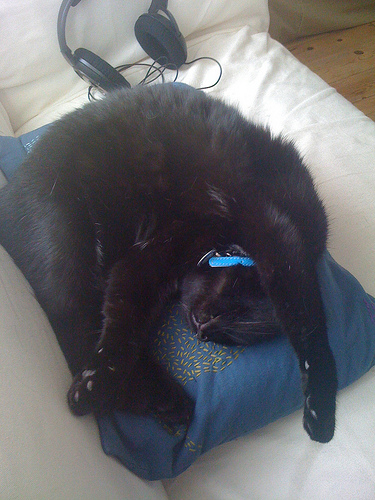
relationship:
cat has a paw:
[4, 90, 337, 444] [70, 350, 118, 408]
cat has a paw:
[4, 90, 337, 444] [298, 365, 339, 444]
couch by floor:
[2, 7, 373, 497] [270, 2, 371, 122]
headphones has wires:
[57, 0, 225, 94] [89, 55, 222, 99]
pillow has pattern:
[2, 84, 375, 483] [142, 293, 271, 452]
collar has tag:
[197, 247, 261, 268] [198, 248, 214, 267]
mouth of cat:
[187, 301, 227, 337] [4, 90, 337, 444]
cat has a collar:
[4, 90, 337, 444] [197, 247, 261, 268]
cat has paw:
[4, 90, 337, 444] [298, 370, 339, 444]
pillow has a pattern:
[2, 84, 375, 483] [142, 293, 271, 452]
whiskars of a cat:
[163, 313, 285, 358] [4, 90, 337, 444]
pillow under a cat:
[2, 84, 375, 483] [4, 90, 337, 444]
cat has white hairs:
[4, 90, 337, 444] [92, 186, 241, 267]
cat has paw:
[4, 90, 337, 444] [70, 350, 118, 408]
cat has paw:
[4, 90, 337, 444] [298, 365, 339, 444]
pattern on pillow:
[142, 293, 271, 452] [2, 84, 375, 483]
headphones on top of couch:
[57, 0, 225, 94] [2, 7, 373, 497]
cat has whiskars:
[4, 90, 337, 444] [163, 313, 285, 358]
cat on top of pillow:
[4, 90, 337, 444] [2, 84, 375, 483]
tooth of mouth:
[210, 313, 216, 318] [187, 301, 227, 337]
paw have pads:
[298, 370, 339, 444] [81, 363, 101, 384]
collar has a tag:
[197, 247, 261, 268] [198, 248, 214, 267]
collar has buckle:
[197, 247, 261, 268] [215, 249, 231, 258]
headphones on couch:
[57, 0, 225, 94] [2, 7, 373, 497]